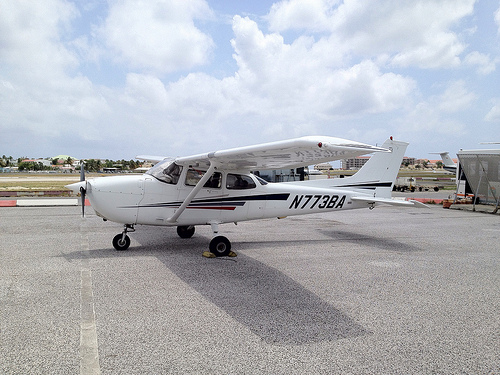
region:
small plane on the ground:
[69, 122, 430, 266]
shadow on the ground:
[159, 264, 367, 359]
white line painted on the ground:
[58, 253, 115, 368]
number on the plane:
[286, 187, 356, 220]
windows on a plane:
[175, 163, 261, 194]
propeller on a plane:
[66, 162, 91, 219]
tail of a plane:
[364, 125, 419, 197]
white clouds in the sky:
[41, 15, 408, 125]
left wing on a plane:
[221, 135, 373, 168]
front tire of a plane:
[107, 221, 141, 258]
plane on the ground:
[72, 105, 438, 264]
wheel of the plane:
[200, 227, 239, 270]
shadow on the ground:
[201, 251, 326, 343]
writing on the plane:
[270, 188, 367, 225]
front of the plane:
[46, 155, 128, 230]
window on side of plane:
[163, 162, 238, 201]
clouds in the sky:
[119, 52, 276, 129]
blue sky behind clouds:
[173, 1, 255, 78]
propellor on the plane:
[54, 159, 111, 222]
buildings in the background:
[17, 133, 84, 180]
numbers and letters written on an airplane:
[289, 191, 347, 211]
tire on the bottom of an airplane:
[206, 229, 235, 261]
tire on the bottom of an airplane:
[108, 228, 133, 250]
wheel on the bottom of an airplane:
[172, 220, 192, 235]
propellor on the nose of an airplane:
[57, 159, 101, 219]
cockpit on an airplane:
[147, 151, 274, 210]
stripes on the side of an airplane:
[116, 190, 295, 216]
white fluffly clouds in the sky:
[169, 19, 364, 111]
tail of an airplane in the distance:
[428, 141, 460, 181]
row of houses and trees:
[3, 148, 132, 174]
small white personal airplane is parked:
[64, 135, 429, 257]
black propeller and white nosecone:
[64, 163, 89, 215]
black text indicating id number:
[289, 195, 346, 209]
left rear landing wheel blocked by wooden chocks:
[201, 235, 236, 258]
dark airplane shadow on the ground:
[51, 224, 423, 346]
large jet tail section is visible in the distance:
[433, 151, 457, 172]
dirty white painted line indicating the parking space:
[79, 215, 100, 374]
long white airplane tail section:
[268, 135, 428, 217]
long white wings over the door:
[135, 135, 390, 221]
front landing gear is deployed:
[112, 223, 136, 250]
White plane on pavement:
[28, 70, 418, 264]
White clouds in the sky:
[16, 17, 69, 63]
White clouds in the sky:
[69, 15, 128, 72]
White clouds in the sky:
[125, 13, 192, 65]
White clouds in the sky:
[189, 10, 261, 70]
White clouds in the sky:
[255, 11, 461, 63]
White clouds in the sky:
[378, 49, 436, 100]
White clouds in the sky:
[392, 96, 487, 141]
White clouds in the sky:
[288, 79, 375, 124]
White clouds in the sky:
[144, 61, 294, 131]